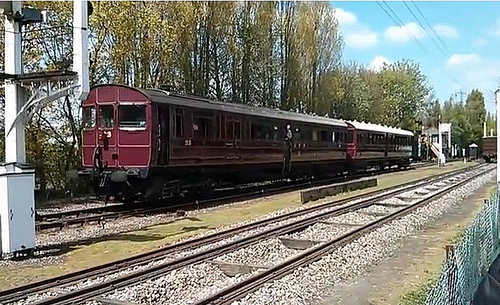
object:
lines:
[376, 1, 494, 98]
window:
[99, 104, 115, 130]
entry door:
[157, 103, 171, 165]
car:
[77, 83, 349, 205]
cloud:
[322, 7, 357, 26]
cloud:
[385, 21, 425, 42]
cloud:
[367, 55, 392, 71]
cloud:
[446, 53, 500, 84]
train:
[81, 83, 414, 205]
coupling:
[77, 86, 152, 182]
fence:
[425, 187, 500, 305]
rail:
[300, 178, 378, 204]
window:
[118, 105, 147, 128]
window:
[82, 105, 97, 130]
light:
[71, 1, 93, 16]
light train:
[0, 1, 93, 255]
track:
[34, 162, 439, 234]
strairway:
[0, 161, 477, 291]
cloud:
[474, 35, 490, 47]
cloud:
[383, 22, 460, 44]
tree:
[462, 88, 488, 157]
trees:
[0, 2, 497, 199]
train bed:
[0, 83, 499, 304]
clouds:
[1, 0, 499, 144]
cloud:
[343, 29, 378, 47]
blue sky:
[328, 1, 500, 116]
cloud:
[319, 7, 376, 46]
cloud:
[429, 23, 457, 38]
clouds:
[318, 7, 500, 120]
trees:
[448, 108, 475, 164]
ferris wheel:
[449, 87, 469, 105]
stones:
[289, 274, 309, 288]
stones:
[367, 236, 383, 250]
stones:
[407, 214, 424, 227]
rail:
[0, 161, 499, 303]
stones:
[186, 270, 214, 281]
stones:
[257, 244, 279, 253]